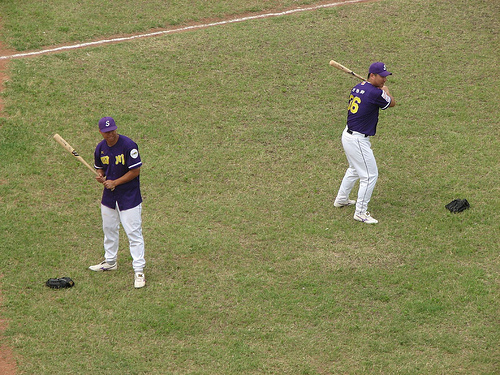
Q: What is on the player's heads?
A: Hats.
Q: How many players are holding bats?
A: 2.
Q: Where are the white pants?
A: On the players.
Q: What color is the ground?
A: Green.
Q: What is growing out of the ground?
A: Grass.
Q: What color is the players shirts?
A: Blue.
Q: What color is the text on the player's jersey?
A: Yellow.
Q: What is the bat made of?
A: Wood.